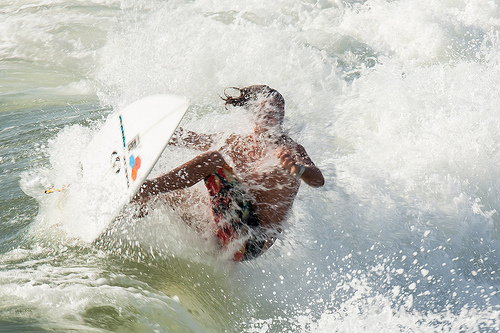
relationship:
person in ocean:
[128, 84, 328, 265] [0, 0, 500, 333]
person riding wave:
[128, 84, 328, 265] [100, 2, 499, 333]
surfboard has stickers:
[23, 90, 194, 251] [107, 106, 152, 191]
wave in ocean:
[100, 2, 499, 333] [0, 0, 500, 333]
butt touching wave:
[212, 230, 283, 264] [100, 2, 499, 333]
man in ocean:
[128, 84, 328, 265] [0, 0, 500, 333]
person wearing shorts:
[128, 84, 328, 265] [201, 160, 271, 263]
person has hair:
[128, 84, 328, 265] [214, 81, 290, 117]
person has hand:
[128, 84, 328, 265] [273, 144, 303, 177]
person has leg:
[128, 84, 328, 265] [131, 148, 260, 265]